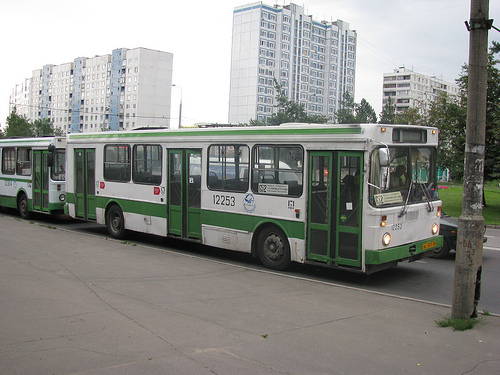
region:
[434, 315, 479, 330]
tuft of grass growing by light pole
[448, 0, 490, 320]
light pole on side of street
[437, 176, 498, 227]
grass growing in park area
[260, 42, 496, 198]
trees growing in park area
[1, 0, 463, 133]
tall white and blue buildings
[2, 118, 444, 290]
white and green buses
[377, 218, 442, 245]
headlights on bus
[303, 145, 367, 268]
green doors on bus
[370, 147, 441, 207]
windshield on front of bus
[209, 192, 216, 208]
number one on bus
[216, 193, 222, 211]
number two on bus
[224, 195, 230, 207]
number five on bus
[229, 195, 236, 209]
number three on bus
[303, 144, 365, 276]
front door of bus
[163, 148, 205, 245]
middle door of bus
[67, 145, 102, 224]
last door on bus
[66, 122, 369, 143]
green strip on bus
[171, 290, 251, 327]
smooth grey side walk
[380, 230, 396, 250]
left light on bus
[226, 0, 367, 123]
high rise building with windows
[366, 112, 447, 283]
front of bus with lights on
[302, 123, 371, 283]
green doors on a bus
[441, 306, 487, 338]
grass at base of pole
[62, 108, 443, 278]
passenger bus with three doors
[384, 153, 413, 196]
bus driver sitting in drivers seat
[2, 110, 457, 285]
two buses parked in a row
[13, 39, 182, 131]
building with blue stripes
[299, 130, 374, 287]
bus doors that are closed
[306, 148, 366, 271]
FRONT GREEN SLIDING BUS DOOR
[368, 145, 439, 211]
BUSES GLASS WINDSHIELD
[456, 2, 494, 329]
STREET POLE OF TELEPHONE POLE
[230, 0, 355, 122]
MULTILEVEL BUILDING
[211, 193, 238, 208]
BUS NUMBER 12253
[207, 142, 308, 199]
TWO FRONT WINDOWS ON BUS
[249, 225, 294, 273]
FRONT PASSANGERS SIDE TIRE ON BUS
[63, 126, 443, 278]
GREEN AND WHITE BUS PARKED ON STREET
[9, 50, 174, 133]
BUILDING IN THE BACKGROUND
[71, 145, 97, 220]
BACK SET OF DOOR ON A BUS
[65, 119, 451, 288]
a green and white city bus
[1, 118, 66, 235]
a green and white city bus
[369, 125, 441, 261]
the front of a city bus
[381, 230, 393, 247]
the headlight on a bus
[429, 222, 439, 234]
the headlight on a bus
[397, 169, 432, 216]
the windshield wipers on a bus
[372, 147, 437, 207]
the windshield of a bus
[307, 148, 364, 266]
the door of a bus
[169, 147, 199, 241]
the door of a bus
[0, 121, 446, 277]
bus is green and white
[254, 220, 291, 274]
wheel is attached to bus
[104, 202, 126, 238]
wheel is attached to bus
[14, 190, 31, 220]
wheel is attached to bus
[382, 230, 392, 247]
headlight is turned on